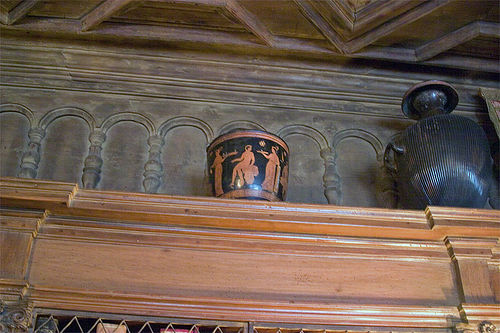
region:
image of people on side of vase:
[213, 137, 285, 200]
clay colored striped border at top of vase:
[203, 128, 294, 152]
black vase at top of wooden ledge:
[375, 74, 495, 211]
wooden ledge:
[4, 172, 497, 331]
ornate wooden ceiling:
[5, 4, 499, 84]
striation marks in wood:
[73, 253, 193, 292]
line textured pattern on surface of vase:
[424, 119, 466, 189]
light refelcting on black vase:
[418, 159, 488, 200]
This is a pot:
[193, 94, 325, 253]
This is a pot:
[359, 48, 496, 261]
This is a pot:
[191, 95, 308, 277]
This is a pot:
[374, 56, 493, 261]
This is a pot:
[197, 114, 314, 252]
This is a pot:
[380, 59, 499, 225]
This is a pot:
[168, 100, 298, 265]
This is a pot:
[385, 67, 497, 239]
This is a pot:
[390, 70, 497, 220]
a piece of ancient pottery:
[207, 128, 287, 201]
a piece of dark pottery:
[382, 79, 492, 209]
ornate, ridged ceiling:
[1, 0, 496, 75]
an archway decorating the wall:
[17, 98, 106, 189]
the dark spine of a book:
[36, 315, 58, 331]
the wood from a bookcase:
[0, 173, 498, 331]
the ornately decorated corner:
[0, 305, 34, 332]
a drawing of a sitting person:
[228, 143, 258, 189]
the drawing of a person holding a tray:
[256, 143, 278, 193]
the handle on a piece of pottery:
[381, 141, 404, 172]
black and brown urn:
[216, 118, 307, 198]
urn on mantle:
[208, 88, 314, 237]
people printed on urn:
[235, 140, 273, 176]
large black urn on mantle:
[390, 56, 477, 188]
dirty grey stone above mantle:
[44, 89, 154, 179]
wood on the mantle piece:
[114, 222, 288, 303]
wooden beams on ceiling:
[253, 8, 330, 42]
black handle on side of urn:
[369, 114, 404, 183]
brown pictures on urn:
[266, 125, 293, 206]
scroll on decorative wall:
[74, 92, 112, 204]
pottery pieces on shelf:
[203, 81, 484, 206]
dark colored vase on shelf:
[365, 51, 496, 203]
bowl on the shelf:
[207, 119, 304, 192]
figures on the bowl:
[218, 142, 286, 191]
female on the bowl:
[256, 140, 280, 186]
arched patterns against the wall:
[5, 99, 365, 201]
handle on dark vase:
[380, 135, 406, 169]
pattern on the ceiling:
[330, 14, 478, 80]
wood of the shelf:
[81, 209, 492, 304]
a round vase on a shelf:
[178, 109, 303, 211]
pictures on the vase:
[196, 119, 291, 203]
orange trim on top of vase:
[205, 123, 285, 147]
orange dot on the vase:
[254, 135, 269, 150]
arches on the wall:
[10, 79, 195, 196]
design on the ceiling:
[29, 0, 479, 72]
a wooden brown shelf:
[3, 155, 480, 328]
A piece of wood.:
[23, 230, 456, 309]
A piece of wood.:
[41, 217, 454, 258]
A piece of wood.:
[57, 210, 442, 242]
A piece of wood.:
[74, 185, 420, 227]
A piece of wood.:
[424, 201, 496, 225]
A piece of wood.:
[436, 240, 497, 307]